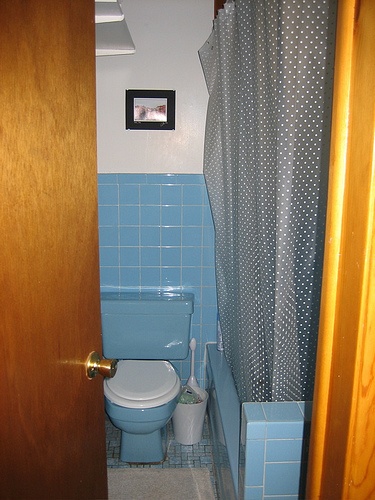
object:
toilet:
[96, 290, 194, 464]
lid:
[103, 356, 180, 410]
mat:
[107, 468, 206, 500]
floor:
[97, 184, 280, 414]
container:
[182, 378, 202, 391]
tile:
[138, 226, 159, 248]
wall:
[97, 0, 213, 293]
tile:
[203, 456, 213, 467]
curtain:
[196, 0, 332, 397]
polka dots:
[285, 178, 290, 186]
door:
[0, 0, 117, 497]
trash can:
[172, 384, 207, 445]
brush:
[186, 336, 198, 389]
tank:
[101, 294, 194, 362]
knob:
[85, 350, 118, 380]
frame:
[307, 0, 375, 499]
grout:
[156, 181, 165, 293]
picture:
[125, 88, 176, 130]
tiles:
[263, 459, 303, 498]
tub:
[207, 343, 305, 499]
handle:
[186, 334, 198, 389]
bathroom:
[92, 0, 328, 497]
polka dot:
[298, 113, 306, 119]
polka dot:
[305, 79, 311, 87]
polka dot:
[309, 39, 315, 47]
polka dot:
[309, 181, 319, 190]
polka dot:
[276, 270, 280, 277]